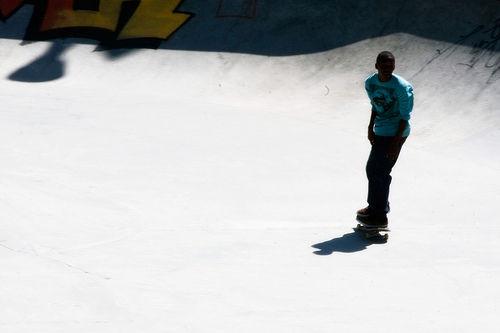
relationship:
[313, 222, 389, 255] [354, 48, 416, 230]
shadow of boy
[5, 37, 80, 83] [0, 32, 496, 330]
shadow on ramp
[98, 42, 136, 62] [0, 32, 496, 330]
shadow on ramp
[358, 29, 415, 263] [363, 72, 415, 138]
boy wearing shirt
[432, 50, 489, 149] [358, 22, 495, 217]
marks on ramp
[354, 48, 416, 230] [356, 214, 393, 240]
boy on a skateboard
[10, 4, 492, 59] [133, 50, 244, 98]
shadow of wall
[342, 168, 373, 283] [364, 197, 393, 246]
front of skateboard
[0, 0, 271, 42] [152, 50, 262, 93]
graffiti on wall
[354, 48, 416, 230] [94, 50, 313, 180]
boy in skateboard bowel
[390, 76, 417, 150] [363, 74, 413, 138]
wrinkles in shirt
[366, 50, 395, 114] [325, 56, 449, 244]
head of boy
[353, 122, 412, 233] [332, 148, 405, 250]
pants worn by skateboarder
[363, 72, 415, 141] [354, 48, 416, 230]
shirt worn by boy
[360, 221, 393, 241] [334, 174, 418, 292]
skateboard being ridden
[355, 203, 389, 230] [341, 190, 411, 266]
shoes worn by skateboarder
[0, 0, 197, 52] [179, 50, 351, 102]
graffiti on ramp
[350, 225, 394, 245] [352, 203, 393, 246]
wheels on skateboard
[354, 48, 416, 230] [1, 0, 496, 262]
boy riding on ramp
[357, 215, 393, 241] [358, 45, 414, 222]
skateboard on boy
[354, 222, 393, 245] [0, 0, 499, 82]
skate in front of ramp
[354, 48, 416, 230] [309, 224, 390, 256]
boy casts shadow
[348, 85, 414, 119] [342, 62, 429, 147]
decal on shirt